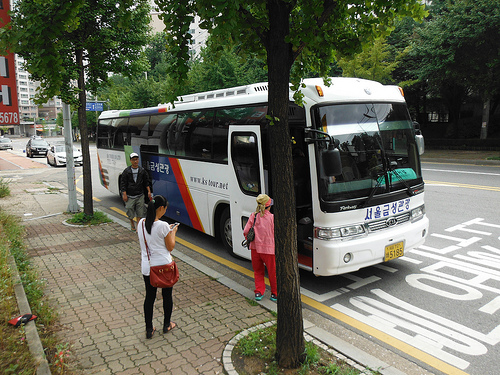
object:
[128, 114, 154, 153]
window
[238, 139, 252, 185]
glass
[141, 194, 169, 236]
hair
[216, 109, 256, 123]
glass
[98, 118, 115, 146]
window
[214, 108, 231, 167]
window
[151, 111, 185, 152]
glass window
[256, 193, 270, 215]
blonde hair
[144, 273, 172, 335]
woman's leggings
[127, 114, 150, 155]
window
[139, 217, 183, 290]
bag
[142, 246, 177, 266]
waist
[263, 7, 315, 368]
trunk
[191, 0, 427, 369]
tree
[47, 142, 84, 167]
car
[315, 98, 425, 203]
front windshield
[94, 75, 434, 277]
bus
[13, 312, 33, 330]
book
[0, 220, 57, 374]
step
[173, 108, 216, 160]
window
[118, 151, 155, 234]
man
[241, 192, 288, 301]
person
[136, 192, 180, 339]
person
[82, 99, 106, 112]
sign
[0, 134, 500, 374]
ground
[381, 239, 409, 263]
license plate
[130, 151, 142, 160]
hat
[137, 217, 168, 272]
back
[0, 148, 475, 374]
sidewalk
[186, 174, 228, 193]
text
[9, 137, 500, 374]
street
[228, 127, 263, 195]
window